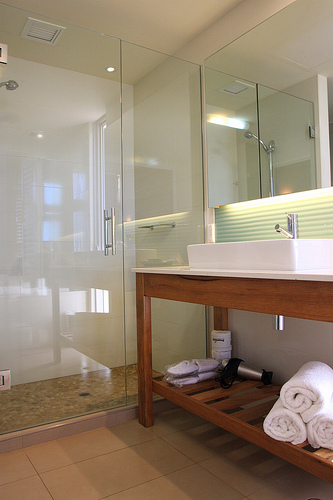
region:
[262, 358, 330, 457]
Three fluffy white bath towels rolled and stacked on bottom shelf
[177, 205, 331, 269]
modern style bathroom sink and faucet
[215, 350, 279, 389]
hair blow dryers on bottom shelf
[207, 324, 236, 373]
two rolls of individually wrapped toilet paper stacked on bottom shelf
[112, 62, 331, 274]
mirror above sink with reflection of shower in it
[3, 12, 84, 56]
overhead vent located in ceiling of shower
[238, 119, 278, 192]
adjustable height shower head seen in mirror's reflection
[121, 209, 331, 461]
bathroom sink supported by wooden fixture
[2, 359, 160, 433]
floor to shower with drain in center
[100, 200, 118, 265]
silver colored handle on shower door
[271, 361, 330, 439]
These are towels.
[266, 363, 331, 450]
The towels are rolled up.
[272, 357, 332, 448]
The towels are white.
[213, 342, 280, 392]
This is a hair dryer.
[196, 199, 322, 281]
This is a sink.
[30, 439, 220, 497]
The ground here is tile.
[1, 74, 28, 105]
This is a shower head.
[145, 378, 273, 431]
This is a made up of wood.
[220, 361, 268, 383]
This is silver and black.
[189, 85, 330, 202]
This is a mirror.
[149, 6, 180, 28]
this is the ceiling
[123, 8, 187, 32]
the ceiling is white in color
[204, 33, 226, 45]
this is the wall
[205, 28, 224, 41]
the wall is white in color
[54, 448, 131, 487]
this is the floor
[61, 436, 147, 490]
the floor is made of tiles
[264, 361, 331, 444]
these are some towels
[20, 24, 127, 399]
this is a door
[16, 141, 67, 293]
the door is made of glass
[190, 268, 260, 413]
this is a table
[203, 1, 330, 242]
A large mirror on the wall.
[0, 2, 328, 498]
A bathroom.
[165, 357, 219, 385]
White slippers.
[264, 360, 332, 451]
Three rolled up white towels.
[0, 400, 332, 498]
Beige colored tile floors.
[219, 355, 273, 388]
A silver and black hair dryer.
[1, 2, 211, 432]
A stand up shower.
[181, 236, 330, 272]
A white bathroom sink.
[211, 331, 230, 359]
Two rolls of toilet paper stacked on top of each other.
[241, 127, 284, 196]
A silver shower head.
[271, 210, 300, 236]
this is a tap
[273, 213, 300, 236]
the tap is metallic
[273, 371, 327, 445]
these are rolls of towels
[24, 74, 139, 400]
the door s made of glass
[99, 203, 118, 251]
this is the handle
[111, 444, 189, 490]
the floor is tiled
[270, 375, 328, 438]
the towels are white in color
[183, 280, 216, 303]
this is a table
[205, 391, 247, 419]
the table is wooden